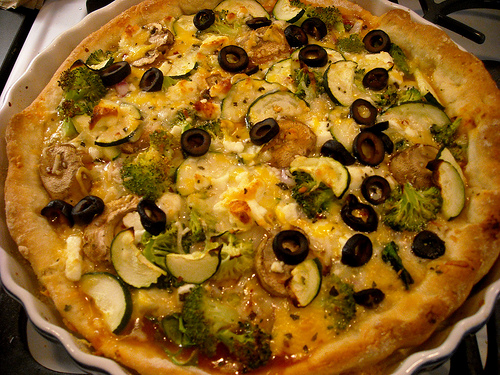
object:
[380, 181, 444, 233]
broccoli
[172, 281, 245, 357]
broccoli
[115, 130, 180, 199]
broccoli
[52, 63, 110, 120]
broccoli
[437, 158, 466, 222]
vegetable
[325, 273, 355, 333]
vegetable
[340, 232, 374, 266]
olive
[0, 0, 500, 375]
pizza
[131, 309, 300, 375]
sauce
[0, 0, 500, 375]
dish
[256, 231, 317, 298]
squash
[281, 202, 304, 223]
cheese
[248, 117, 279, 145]
olive